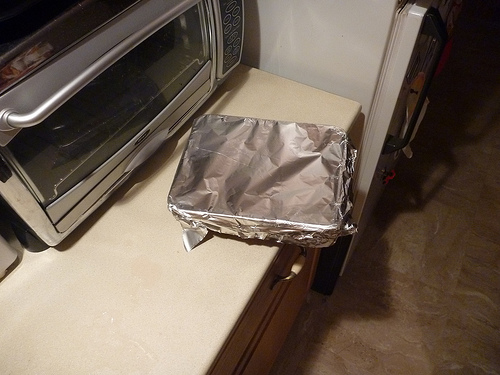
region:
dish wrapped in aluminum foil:
[166, 102, 382, 265]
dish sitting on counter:
[186, 99, 362, 261]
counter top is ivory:
[3, 79, 363, 373]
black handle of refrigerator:
[381, 35, 430, 190]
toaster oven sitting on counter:
[1, 0, 275, 230]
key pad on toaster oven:
[214, 3, 261, 83]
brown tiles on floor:
[270, 203, 497, 374]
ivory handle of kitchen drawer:
[272, 237, 312, 297]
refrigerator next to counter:
[256, 5, 461, 320]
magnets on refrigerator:
[348, 7, 478, 241]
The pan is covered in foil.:
[169, 102, 353, 254]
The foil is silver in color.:
[165, 107, 347, 249]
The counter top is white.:
[52, 296, 174, 373]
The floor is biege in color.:
[414, 254, 494, 370]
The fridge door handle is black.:
[387, 15, 453, 171]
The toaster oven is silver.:
[7, 2, 185, 244]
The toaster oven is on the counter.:
[7, 12, 187, 253]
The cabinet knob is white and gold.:
[275, 248, 313, 287]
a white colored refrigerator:
[164, 0, 464, 300]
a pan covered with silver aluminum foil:
[166, 111, 356, 251]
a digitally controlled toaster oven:
[1, 0, 248, 252]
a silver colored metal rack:
[38, 53, 207, 201]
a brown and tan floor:
[276, 4, 499, 372]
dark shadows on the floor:
[270, 0, 499, 372]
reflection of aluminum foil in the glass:
[12, 28, 208, 223]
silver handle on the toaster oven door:
[8, 0, 202, 133]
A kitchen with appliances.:
[2, 1, 494, 368]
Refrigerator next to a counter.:
[250, 1, 455, 298]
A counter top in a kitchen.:
[8, 58, 363, 373]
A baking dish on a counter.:
[168, 107, 361, 253]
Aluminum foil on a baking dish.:
[167, 109, 361, 252]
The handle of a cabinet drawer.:
[272, 238, 314, 291]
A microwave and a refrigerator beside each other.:
[2, 4, 461, 299]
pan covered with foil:
[171, 105, 356, 271]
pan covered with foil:
[161, 96, 376, 293]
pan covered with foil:
[163, 108, 413, 306]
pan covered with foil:
[164, 103, 361, 281]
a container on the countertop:
[148, 80, 374, 278]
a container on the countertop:
[166, 99, 370, 273]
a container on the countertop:
[158, 103, 353, 268]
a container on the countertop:
[156, 83, 368, 279]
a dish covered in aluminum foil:
[155, 106, 367, 248]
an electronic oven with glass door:
[1, 0, 261, 234]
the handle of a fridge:
[346, 6, 436, 189]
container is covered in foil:
[164, 111, 354, 260]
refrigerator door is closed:
[325, 3, 461, 293]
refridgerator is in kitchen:
[244, 0, 461, 299]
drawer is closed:
[208, 115, 360, 373]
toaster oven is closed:
[2, 0, 251, 254]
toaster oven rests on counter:
[0, 0, 247, 251]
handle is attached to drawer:
[272, 240, 310, 290]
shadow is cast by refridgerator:
[368, 1, 498, 241]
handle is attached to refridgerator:
[387, 7, 447, 157]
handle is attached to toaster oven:
[1, 0, 203, 139]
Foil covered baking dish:
[161, 109, 360, 251]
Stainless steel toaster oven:
[6, 5, 256, 253]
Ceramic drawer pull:
[273, 247, 313, 292]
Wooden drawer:
[231, 247, 314, 353]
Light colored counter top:
[3, 55, 372, 373]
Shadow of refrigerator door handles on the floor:
[410, 97, 490, 227]